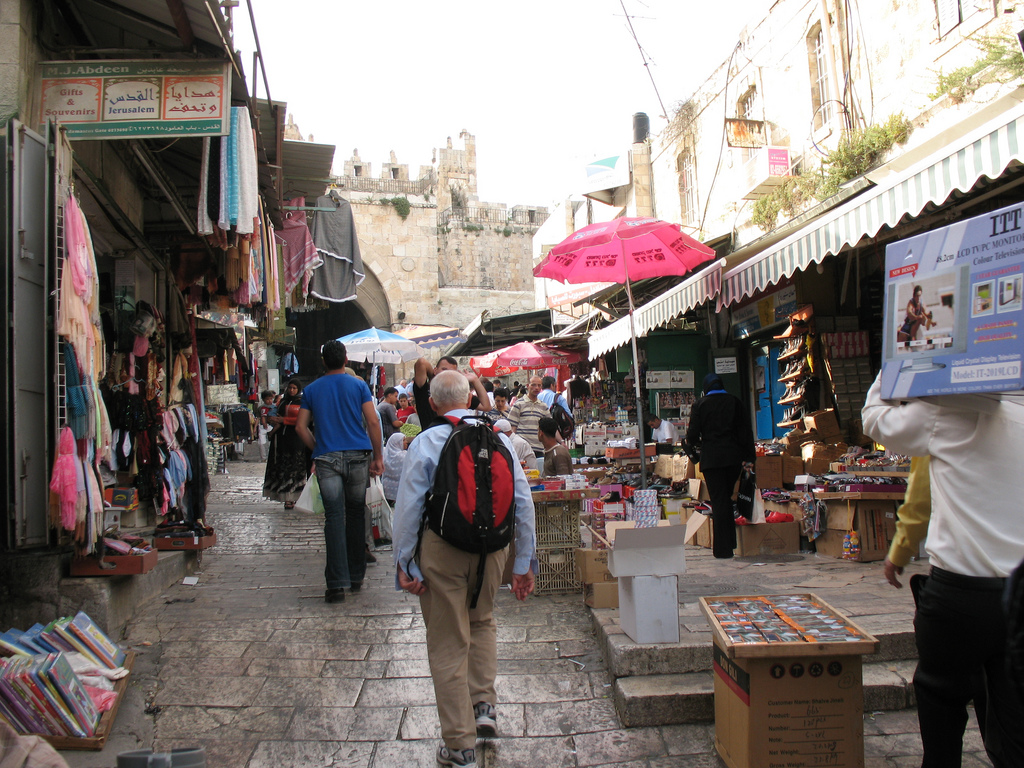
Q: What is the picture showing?
A: It is showing a market.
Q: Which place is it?
A: It is a market.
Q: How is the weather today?
A: It is overcast.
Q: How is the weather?
A: It is overcast.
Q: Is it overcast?
A: Yes, it is overcast.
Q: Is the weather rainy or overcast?
A: It is overcast.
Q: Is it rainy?
A: No, it is overcast.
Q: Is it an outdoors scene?
A: Yes, it is outdoors.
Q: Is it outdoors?
A: Yes, it is outdoors.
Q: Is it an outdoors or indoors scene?
A: It is outdoors.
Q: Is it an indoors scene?
A: No, it is outdoors.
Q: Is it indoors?
A: No, it is outdoors.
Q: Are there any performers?
A: No, there are no performers.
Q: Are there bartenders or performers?
A: No, there are no performers or bartenders.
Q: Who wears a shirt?
A: The man wears a shirt.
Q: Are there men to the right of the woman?
A: Yes, there is a man to the right of the woman.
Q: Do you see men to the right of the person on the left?
A: Yes, there is a man to the right of the woman.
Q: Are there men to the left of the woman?
A: No, the man is to the right of the woman.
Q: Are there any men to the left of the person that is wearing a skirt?
A: No, the man is to the right of the woman.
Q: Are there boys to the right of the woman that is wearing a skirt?
A: No, there is a man to the right of the woman.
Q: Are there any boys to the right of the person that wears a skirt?
A: No, there is a man to the right of the woman.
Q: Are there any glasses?
A: No, there are no glasses.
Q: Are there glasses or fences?
A: No, there are no glasses or fences.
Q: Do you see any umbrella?
A: Yes, there is an umbrella.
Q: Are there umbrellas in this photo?
A: Yes, there is an umbrella.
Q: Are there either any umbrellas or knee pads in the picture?
A: Yes, there is an umbrella.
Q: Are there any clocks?
A: No, there are no clocks.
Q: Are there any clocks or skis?
A: No, there are no clocks or skis.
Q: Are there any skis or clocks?
A: No, there are no clocks or skis.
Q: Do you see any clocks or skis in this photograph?
A: No, there are no clocks or skis.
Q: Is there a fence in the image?
A: No, there are no fences.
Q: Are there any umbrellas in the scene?
A: Yes, there is an umbrella.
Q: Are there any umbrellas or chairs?
A: Yes, there is an umbrella.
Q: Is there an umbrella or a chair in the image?
A: Yes, there is an umbrella.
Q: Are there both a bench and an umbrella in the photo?
A: No, there is an umbrella but no benches.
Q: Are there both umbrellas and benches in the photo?
A: No, there is an umbrella but no benches.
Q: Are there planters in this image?
A: No, there are no planters.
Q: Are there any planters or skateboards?
A: No, there are no planters or skateboards.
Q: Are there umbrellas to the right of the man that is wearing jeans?
A: Yes, there is an umbrella to the right of the man.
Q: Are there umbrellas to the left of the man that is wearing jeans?
A: No, the umbrella is to the right of the man.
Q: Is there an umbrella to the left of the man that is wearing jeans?
A: No, the umbrella is to the right of the man.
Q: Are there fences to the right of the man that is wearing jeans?
A: No, there is an umbrella to the right of the man.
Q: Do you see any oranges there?
A: No, there are no oranges.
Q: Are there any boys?
A: No, there are no boys.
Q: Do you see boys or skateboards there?
A: No, there are no boys or skateboards.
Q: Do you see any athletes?
A: No, there are no athletes.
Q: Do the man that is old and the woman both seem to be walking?
A: Yes, both the man and the woman are walking.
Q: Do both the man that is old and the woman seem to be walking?
A: Yes, both the man and the woman are walking.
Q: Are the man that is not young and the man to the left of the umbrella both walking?
A: Yes, both the man and the man are walking.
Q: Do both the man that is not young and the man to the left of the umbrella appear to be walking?
A: Yes, both the man and the man are walking.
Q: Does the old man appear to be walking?
A: Yes, the man is walking.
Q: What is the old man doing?
A: The man is walking.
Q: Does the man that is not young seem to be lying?
A: No, the man is walking.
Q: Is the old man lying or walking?
A: The man is walking.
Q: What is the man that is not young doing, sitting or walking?
A: The man is walking.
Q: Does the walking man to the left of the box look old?
A: Yes, the man is old.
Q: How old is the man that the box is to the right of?
A: The man is old.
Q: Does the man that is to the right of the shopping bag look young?
A: No, the man is old.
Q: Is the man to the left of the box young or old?
A: The man is old.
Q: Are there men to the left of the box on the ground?
A: Yes, there is a man to the left of the box.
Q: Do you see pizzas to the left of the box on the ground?
A: No, there is a man to the left of the box.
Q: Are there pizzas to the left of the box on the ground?
A: No, there is a man to the left of the box.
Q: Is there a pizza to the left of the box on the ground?
A: No, there is a man to the left of the box.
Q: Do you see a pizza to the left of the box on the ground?
A: No, there is a man to the left of the box.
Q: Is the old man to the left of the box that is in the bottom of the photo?
A: Yes, the man is to the left of the box.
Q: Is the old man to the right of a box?
A: No, the man is to the left of a box.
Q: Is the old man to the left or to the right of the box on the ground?
A: The man is to the left of the box.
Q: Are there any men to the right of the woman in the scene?
A: Yes, there is a man to the right of the woman.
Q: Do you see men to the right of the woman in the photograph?
A: Yes, there is a man to the right of the woman.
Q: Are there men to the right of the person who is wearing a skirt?
A: Yes, there is a man to the right of the woman.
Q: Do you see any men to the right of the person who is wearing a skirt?
A: Yes, there is a man to the right of the woman.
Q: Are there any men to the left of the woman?
A: No, the man is to the right of the woman.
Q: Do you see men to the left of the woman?
A: No, the man is to the right of the woman.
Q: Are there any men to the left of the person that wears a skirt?
A: No, the man is to the right of the woman.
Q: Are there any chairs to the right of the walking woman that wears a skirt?
A: No, there is a man to the right of the woman.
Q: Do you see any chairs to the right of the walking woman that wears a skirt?
A: No, there is a man to the right of the woman.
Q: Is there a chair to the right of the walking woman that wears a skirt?
A: No, there is a man to the right of the woman.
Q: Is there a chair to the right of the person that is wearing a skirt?
A: No, there is a man to the right of the woman.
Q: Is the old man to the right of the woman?
A: Yes, the man is to the right of the woman.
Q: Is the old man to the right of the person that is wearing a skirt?
A: Yes, the man is to the right of the woman.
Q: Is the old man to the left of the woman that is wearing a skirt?
A: No, the man is to the right of the woman.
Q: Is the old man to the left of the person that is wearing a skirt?
A: No, the man is to the right of the woman.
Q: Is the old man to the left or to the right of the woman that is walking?
A: The man is to the right of the woman.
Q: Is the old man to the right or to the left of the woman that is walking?
A: The man is to the right of the woman.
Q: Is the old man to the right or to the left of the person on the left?
A: The man is to the right of the woman.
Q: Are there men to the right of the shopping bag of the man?
A: Yes, there is a man to the right of the shopping bag.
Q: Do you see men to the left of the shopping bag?
A: No, the man is to the right of the shopping bag.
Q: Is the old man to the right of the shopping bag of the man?
A: Yes, the man is to the right of the shopping bag.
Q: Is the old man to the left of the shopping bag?
A: No, the man is to the right of the shopping bag.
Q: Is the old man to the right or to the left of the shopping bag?
A: The man is to the right of the shopping bag.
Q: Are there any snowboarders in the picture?
A: No, there are no snowboarders.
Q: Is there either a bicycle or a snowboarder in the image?
A: No, there are no snowboarders or bicycles.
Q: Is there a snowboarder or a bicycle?
A: No, there are no snowboarders or bicycles.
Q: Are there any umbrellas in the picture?
A: Yes, there is an umbrella.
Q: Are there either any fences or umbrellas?
A: Yes, there is an umbrella.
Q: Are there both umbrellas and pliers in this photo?
A: No, there is an umbrella but no pliers.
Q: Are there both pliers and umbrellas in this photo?
A: No, there is an umbrella but no pliers.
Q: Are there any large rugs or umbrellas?
A: Yes, there is a large umbrella.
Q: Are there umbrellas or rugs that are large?
A: Yes, the umbrella is large.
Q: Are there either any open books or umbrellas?
A: Yes, there is an open umbrella.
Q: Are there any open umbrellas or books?
A: Yes, there is an open umbrella.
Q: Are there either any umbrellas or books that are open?
A: Yes, the umbrella is open.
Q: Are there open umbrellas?
A: Yes, there is an open umbrella.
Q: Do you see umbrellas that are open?
A: Yes, there is an open umbrella.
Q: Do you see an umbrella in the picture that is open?
A: Yes, there is an umbrella that is open.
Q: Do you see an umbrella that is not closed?
A: Yes, there is a open umbrella.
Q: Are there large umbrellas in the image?
A: Yes, there is a large umbrella.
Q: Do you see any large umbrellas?
A: Yes, there is a large umbrella.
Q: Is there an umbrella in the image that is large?
A: Yes, there is an umbrella that is large.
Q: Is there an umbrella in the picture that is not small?
A: Yes, there is a large umbrella.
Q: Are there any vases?
A: No, there are no vases.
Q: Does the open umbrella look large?
A: Yes, the umbrella is large.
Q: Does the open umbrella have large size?
A: Yes, the umbrella is large.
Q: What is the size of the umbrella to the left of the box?
A: The umbrella is large.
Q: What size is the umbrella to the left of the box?
A: The umbrella is large.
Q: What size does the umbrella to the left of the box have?
A: The umbrella has large size.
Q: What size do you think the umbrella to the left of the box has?
A: The umbrella has large size.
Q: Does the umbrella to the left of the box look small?
A: No, the umbrella is large.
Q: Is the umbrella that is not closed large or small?
A: The umbrella is large.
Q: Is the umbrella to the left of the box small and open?
A: No, the umbrella is open but large.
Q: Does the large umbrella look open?
A: Yes, the umbrella is open.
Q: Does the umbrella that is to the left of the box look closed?
A: No, the umbrella is open.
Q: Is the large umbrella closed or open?
A: The umbrella is open.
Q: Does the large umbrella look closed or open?
A: The umbrella is open.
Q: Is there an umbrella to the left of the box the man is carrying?
A: Yes, there is an umbrella to the left of the box.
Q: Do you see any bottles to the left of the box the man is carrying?
A: No, there is an umbrella to the left of the box.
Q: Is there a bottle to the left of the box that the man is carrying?
A: No, there is an umbrella to the left of the box.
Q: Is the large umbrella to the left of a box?
A: Yes, the umbrella is to the left of a box.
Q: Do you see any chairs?
A: No, there are no chairs.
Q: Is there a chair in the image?
A: No, there are no chairs.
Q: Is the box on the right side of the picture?
A: Yes, the box is on the right of the image.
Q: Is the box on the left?
A: No, the box is on the right of the image.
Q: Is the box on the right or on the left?
A: The box is on the right of the image.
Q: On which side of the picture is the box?
A: The box is on the right of the image.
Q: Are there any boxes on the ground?
A: Yes, there is a box on the ground.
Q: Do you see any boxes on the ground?
A: Yes, there is a box on the ground.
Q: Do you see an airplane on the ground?
A: No, there is a box on the ground.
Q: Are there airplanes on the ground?
A: No, there is a box on the ground.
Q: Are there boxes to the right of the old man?
A: Yes, there is a box to the right of the man.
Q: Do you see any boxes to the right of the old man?
A: Yes, there is a box to the right of the man.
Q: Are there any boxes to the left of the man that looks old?
A: No, the box is to the right of the man.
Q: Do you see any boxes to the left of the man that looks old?
A: No, the box is to the right of the man.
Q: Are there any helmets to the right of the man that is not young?
A: No, there is a box to the right of the man.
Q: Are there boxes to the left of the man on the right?
A: Yes, there is a box to the left of the man.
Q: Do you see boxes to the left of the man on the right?
A: Yes, there is a box to the left of the man.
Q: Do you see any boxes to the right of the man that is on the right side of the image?
A: No, the box is to the left of the man.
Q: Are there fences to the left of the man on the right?
A: No, there is a box to the left of the man.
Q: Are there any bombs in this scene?
A: No, there are no bombs.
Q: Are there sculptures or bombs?
A: No, there are no bombs or sculptures.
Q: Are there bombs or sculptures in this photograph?
A: No, there are no bombs or sculptures.